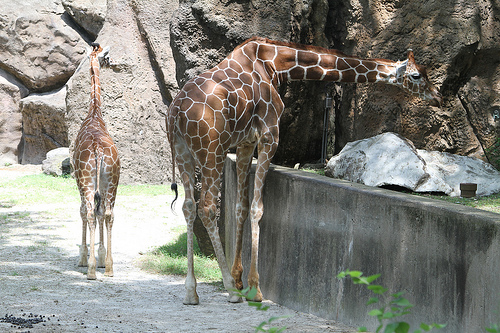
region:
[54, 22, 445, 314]
two giraffes in a pen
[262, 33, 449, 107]
long neck of giraffe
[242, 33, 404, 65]
mane of giraffe is brown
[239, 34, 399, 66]
mane of giraffe is short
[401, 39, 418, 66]
horns of giraffe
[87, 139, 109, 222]
tail of giraffe has black turf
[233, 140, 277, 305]
front legs of giraffe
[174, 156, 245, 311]
back legs of giraffe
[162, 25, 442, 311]
neck of giraffe is bend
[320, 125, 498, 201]
big stones color white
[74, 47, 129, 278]
Baby giraffe standing in the sun.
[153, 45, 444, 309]
Mother giraffe standing in the shade.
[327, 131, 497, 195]
Huge white rock in a giraffe exhibit.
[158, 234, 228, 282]
Patch of green grass in the sun.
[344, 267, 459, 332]
Green weeds growing along the wall.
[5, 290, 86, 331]
Black giraffe turds spread on the ground.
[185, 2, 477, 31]
Brown rocks located in a zoo exhibit.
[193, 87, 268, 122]
Brown and white print of a giraffe's hide.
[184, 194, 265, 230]
Giraffe's knobby knees on long legs.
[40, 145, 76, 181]
A large rock in the sunlight.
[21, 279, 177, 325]
The ground is made of dirt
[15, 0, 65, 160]
A very large boulder rock wall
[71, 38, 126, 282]
A baby calf walking away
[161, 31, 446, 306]
The giraffe is an adult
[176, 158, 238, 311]
The hind legs of the giraffe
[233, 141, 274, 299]
The front legs of the giraffe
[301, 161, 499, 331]
A low cement wall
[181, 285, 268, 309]
The feet of the giraffe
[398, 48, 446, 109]
The head of the giraffe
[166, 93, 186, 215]
The tail of the giraffe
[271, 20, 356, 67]
Brown hair on the giraffe's neck.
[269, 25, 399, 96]
Giraffe has long neck.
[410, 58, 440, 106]
Giraffe has large dark eye.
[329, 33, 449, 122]
Giraffe is bending head down near rock.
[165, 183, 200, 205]
Black hair at the end of tail.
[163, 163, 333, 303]
Giraffe standing near concrete wall.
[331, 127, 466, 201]
Large gray rock near giraffe's head.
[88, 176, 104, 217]
Long black hair on end of tail.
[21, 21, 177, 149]
Large rock wall behind giraffes.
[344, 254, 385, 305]
Green leaves on plant.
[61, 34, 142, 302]
This is a giraffe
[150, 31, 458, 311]
This is a giraffe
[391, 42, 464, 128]
Head of a giraffe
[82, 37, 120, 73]
Head of a giraffe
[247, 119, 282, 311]
Leg of a giraffe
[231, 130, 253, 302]
Leg of a giraffe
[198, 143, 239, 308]
Leg of a giraffe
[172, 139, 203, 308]
Leg of a giraffe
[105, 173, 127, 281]
Leg of a giraffe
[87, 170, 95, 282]
Leg of a giraffe